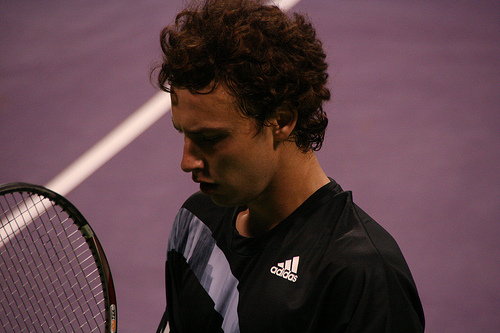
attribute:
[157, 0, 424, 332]
player — professional, male, white, young, playing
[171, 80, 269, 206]
face — concentrating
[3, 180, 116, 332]
raquet — partial, tennis, brown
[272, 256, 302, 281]
logo — adidas, white, small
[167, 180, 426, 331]
shirt — black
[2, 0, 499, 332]
court — hard, purple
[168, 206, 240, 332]
stripe — grey, lilac, gray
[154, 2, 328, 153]
hair — brown, curly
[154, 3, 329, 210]
head — tilted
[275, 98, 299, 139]
ear — poking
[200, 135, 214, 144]
eye — looking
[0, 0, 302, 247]
stripe — white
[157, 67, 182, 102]
curl — brown